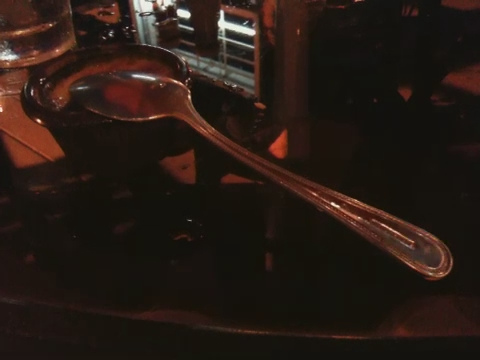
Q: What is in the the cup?
A: Soup.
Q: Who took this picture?
A: The homeowner.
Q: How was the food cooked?
A: The stove.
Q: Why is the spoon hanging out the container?
A: About to be used.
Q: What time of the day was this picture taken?
A: At night.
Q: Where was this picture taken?
A: The kitchen.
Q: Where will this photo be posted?
A: Facebook.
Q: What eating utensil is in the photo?
A: Spoon.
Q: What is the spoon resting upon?
A: A black bowl of sauce.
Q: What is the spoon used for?
A: To stir the sauce.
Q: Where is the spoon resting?
A: On the black bowl with sauce.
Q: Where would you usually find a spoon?
A: In the kitchen.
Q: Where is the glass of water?
A: On the tile counter.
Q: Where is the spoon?
A: The spoon is resting on the bowl.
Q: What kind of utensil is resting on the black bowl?
A: A spoon is resting on the black bowl.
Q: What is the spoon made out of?
A: The spoon is made of metal.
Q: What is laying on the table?
A: A large spoon.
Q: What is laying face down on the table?
A: A silver spoon.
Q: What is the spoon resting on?
A: A small bowl.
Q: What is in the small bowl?
A: Dipping sauce.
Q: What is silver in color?
A: The spoon.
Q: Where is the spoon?
A: On a surface.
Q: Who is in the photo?
A: No people.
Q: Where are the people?
A: None in photo.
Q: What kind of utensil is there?
A: Spoon.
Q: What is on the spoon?
A: Cream.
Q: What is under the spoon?
A: Table.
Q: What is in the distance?
A: A light.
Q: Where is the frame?
A: On window.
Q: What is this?
A: A spoon.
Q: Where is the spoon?
A: On the table.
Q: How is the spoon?
A: Turned upside down.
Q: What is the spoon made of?
A: Silver.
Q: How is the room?
A: Dark.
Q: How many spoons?
A: One.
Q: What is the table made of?
A: Wood.